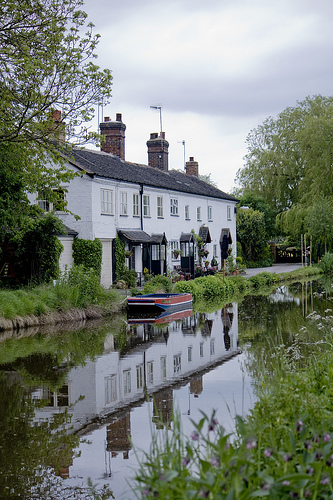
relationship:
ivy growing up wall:
[108, 236, 124, 280] [80, 212, 137, 304]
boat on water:
[124, 290, 194, 319] [158, 336, 170, 340]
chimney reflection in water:
[104, 408, 133, 460] [132, 402, 150, 429]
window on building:
[100, 185, 115, 217] [27, 103, 240, 277]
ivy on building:
[73, 237, 100, 272] [27, 103, 240, 277]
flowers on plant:
[201, 422, 323, 498] [206, 432, 310, 494]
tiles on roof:
[98, 150, 123, 171] [60, 143, 241, 201]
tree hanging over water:
[0, 0, 118, 270] [83, 340, 108, 358]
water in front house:
[171, 357, 197, 373] [10, 107, 242, 268]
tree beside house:
[0, 0, 118, 270] [5, 118, 247, 274]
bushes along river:
[173, 273, 274, 298] [244, 306, 288, 326]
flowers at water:
[164, 395, 274, 497] [6, 277, 331, 497]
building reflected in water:
[41, 301, 240, 452] [6, 277, 331, 497]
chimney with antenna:
[186, 155, 199, 174] [180, 140, 187, 171]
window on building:
[156, 195, 166, 218] [6, 125, 239, 278]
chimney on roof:
[102, 113, 128, 156] [13, 121, 243, 203]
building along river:
[0, 109, 241, 294] [8, 275, 328, 499]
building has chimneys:
[0, 109, 241, 294] [42, 103, 201, 181]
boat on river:
[120, 285, 199, 315] [8, 275, 328, 499]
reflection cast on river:
[26, 297, 234, 497] [8, 275, 328, 499]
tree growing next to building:
[3, 115, 72, 260] [0, 109, 241, 294]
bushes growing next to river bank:
[177, 273, 242, 302] [0, 258, 314, 329]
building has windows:
[0, 109, 241, 294] [96, 185, 237, 226]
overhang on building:
[117, 224, 165, 245] [34, 108, 251, 289]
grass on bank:
[2, 304, 110, 333] [1, 285, 135, 329]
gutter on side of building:
[131, 181, 147, 194] [22, 103, 258, 292]